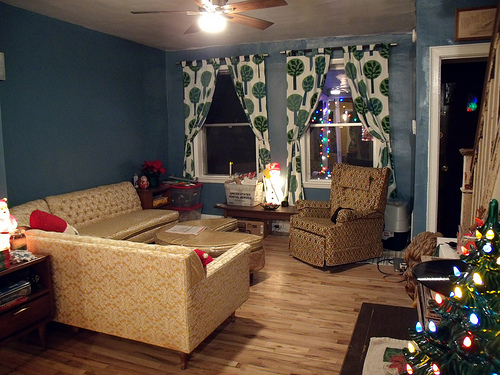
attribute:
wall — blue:
[424, 14, 452, 42]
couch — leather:
[83, 239, 215, 338]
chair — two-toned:
[292, 164, 386, 265]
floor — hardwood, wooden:
[272, 334, 316, 369]